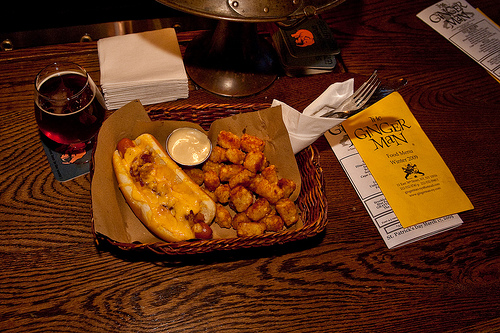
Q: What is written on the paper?
A: The Ginger Man.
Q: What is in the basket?
A: Food.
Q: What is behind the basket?
A: A stack of napkins.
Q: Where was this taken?
A: Maybe the Ginger Man restaurant.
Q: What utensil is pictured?
A: A fork.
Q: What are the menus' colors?
A: Yellow and white.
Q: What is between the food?
A: Condiment.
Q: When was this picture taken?
A: Maybe dinner time.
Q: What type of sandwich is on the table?
A: Hot Dog.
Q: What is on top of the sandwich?
A: Cheese.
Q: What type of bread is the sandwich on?
A: Bun.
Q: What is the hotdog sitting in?
A: Basket.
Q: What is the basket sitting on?
A: Table.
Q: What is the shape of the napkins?
A: Square.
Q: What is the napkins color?
A: White.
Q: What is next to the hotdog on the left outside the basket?
A: Wine glass.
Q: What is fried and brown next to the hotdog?
A: Tater tots.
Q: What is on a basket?
A: A sandwich.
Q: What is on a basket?
A: A sandwich.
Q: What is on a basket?
A: A sandwich.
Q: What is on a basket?
A: A sandwich.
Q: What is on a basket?
A: A sandwich.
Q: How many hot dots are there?
A: One.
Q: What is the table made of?
A: Wood.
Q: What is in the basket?
A: Tater tots.